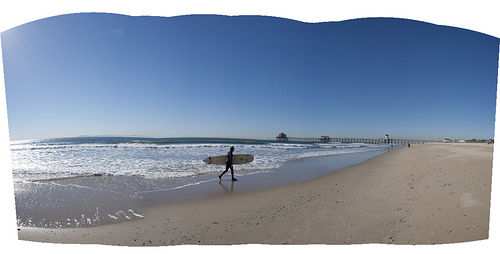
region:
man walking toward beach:
[189, 139, 259, 196]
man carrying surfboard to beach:
[172, 144, 267, 194]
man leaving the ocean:
[198, 133, 275, 199]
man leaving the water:
[198, 135, 262, 205]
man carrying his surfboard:
[176, 125, 261, 217]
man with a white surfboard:
[163, 133, 285, 222]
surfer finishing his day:
[180, 129, 272, 219]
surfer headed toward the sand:
[183, 135, 277, 198]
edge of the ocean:
[249, 141, 405, 215]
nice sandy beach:
[312, 138, 474, 245]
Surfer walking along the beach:
[191, 125, 273, 202]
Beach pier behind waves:
[265, 39, 413, 184]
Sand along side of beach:
[296, 140, 463, 235]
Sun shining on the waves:
[0, 127, 217, 202]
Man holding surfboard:
[195, 143, 250, 183]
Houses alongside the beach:
[432, 130, 489, 168]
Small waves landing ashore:
[249, 141, 390, 185]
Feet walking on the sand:
[185, 167, 307, 211]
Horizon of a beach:
[6, 107, 268, 147]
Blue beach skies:
[7, 25, 495, 135]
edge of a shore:
[427, 187, 442, 197]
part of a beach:
[313, 196, 348, 216]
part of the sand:
[411, 157, 420, 175]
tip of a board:
[248, 145, 249, 165]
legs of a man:
[217, 172, 236, 174]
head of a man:
[226, 142, 236, 157]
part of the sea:
[124, 160, 144, 206]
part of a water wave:
[88, 25, 123, 154]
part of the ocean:
[366, 130, 368, 147]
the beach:
[94, 67, 344, 247]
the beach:
[71, 68, 260, 195]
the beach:
[108, 48, 245, 155]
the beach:
[67, 5, 242, 245]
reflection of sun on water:
[17, 141, 46, 167]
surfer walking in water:
[206, 142, 251, 196]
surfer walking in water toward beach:
[204, 141, 253, 186]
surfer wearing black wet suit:
[218, 144, 240, 188]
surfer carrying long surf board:
[209, 143, 259, 165]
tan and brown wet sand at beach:
[70, 183, 190, 224]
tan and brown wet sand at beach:
[247, 163, 342, 211]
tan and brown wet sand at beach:
[323, 144, 403, 198]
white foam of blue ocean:
[54, 141, 156, 180]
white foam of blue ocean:
[275, 143, 336, 175]